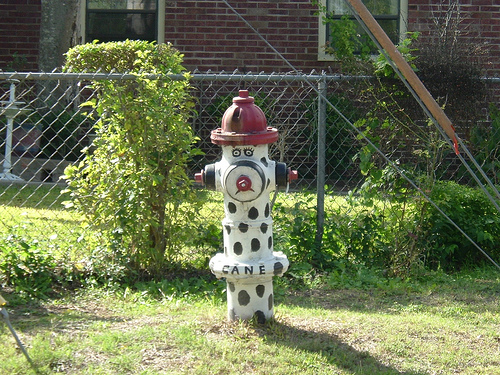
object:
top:
[211, 91, 280, 145]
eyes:
[232, 147, 245, 158]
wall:
[167, 5, 317, 73]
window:
[79, 0, 168, 49]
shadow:
[264, 320, 402, 374]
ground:
[0, 276, 498, 368]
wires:
[342, 0, 497, 266]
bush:
[49, 30, 207, 291]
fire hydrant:
[195, 89, 298, 325]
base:
[224, 289, 276, 325]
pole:
[313, 76, 328, 280]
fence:
[0, 69, 498, 279]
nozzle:
[272, 156, 300, 188]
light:
[41, 213, 75, 242]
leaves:
[18, 237, 40, 254]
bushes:
[4, 218, 56, 306]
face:
[226, 140, 269, 210]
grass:
[1, 270, 493, 372]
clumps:
[90, 332, 175, 372]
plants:
[280, 196, 350, 270]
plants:
[0, 229, 78, 320]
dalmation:
[233, 239, 246, 257]